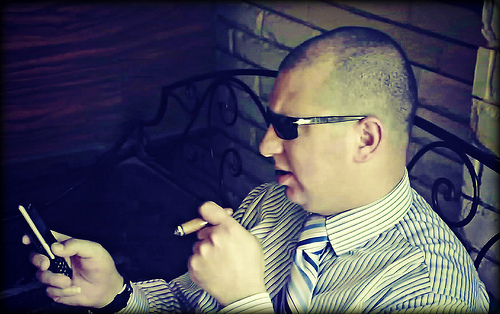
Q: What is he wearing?
A: Glasses.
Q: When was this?
A: Nighttime.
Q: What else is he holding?
A: A phone.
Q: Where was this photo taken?
A: On a bench.